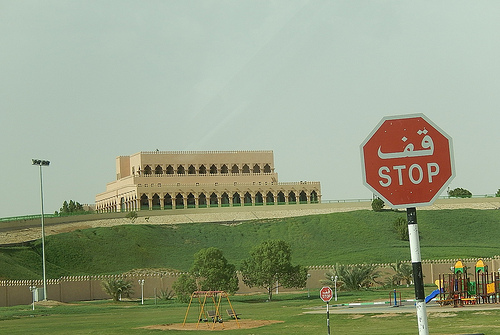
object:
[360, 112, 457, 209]
stop sign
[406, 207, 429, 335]
pole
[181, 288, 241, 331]
swing set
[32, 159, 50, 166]
light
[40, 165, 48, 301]
pole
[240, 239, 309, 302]
tree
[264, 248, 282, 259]
leaves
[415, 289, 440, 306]
slide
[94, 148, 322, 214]
building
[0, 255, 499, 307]
fence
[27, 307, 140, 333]
grass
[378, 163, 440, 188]
letters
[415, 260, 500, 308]
playground equipment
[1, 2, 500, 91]
sky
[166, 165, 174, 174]
window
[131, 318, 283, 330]
patch of dirt